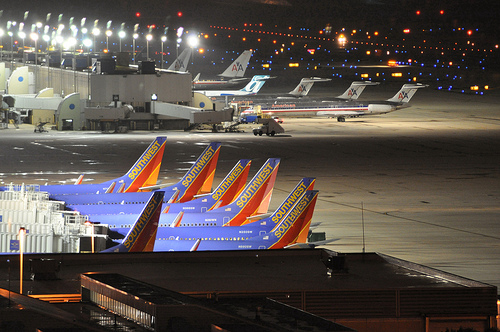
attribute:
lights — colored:
[278, 41, 417, 76]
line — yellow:
[338, 204, 498, 212]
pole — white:
[8, 221, 33, 302]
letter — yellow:
[273, 221, 286, 242]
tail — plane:
[251, 180, 327, 247]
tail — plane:
[261, 178, 329, 270]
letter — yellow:
[269, 221, 294, 240]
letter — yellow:
[275, 221, 285, 240]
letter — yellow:
[280, 213, 297, 242]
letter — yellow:
[286, 210, 296, 225]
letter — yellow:
[294, 207, 321, 231]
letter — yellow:
[252, 172, 262, 186]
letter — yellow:
[299, 195, 304, 207]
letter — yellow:
[281, 199, 290, 209]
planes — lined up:
[4, 128, 336, 258]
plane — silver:
[257, 74, 429, 124]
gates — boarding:
[2, 179, 109, 255]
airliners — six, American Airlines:
[72, 25, 432, 158]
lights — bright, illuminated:
[7, 13, 235, 67]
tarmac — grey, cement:
[300, 114, 494, 237]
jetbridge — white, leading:
[135, 87, 223, 131]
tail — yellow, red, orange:
[108, 131, 209, 191]